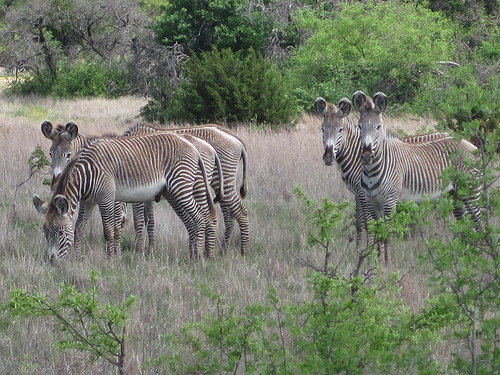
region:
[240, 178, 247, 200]
The bushy tip of a zebra's tail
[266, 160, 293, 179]
Tall dry brown grass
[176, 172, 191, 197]
Brown and white stripe on a zebra's flank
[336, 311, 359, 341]
Small green leaves on a scrub bush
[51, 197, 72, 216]
A zebra's ear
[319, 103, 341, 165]
A zebra's muzzle, facing forward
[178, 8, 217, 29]
Green leaves on a tree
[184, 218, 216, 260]
Three zebra hind legs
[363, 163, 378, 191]
Brown and white stripe pattern on a zebra's neck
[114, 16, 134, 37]
Bare tree branches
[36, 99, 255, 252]
zebras in the field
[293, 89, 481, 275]
zebras in the field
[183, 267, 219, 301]
dry grass in field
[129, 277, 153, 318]
dry grass in field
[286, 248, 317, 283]
dry grass in field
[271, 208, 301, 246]
dry grass in field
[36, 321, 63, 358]
dry grass in field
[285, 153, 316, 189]
dry grass in field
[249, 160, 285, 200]
dry grass in field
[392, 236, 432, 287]
dry grass in field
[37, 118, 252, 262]
A pair of zebras grazing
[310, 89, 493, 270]
A pair of zebras staring at photographer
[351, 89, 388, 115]
Pair of round zebra ears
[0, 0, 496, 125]
Trees behind the zebras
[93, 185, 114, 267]
Stripes on zebra leg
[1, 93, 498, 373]
Grassy area for grazing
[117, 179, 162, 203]
Solid white patch on zebra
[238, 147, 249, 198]
Skinny zebra tail with furry end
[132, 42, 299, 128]
Tall green bush behind zebras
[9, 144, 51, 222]
Small tree branch beside zebra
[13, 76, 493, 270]
several zebra in the wild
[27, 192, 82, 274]
the head of a zebra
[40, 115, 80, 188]
the head of a zebra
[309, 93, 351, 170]
the head of a zebra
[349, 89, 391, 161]
the head of a zebra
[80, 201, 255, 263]
the legs of three zebras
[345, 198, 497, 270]
the legs of two zebras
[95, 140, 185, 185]
the stripes of a zebra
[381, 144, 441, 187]
the stripes of a zebra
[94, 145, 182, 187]
the fur of a zebra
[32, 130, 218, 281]
A zebra eating.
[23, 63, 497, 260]
zebras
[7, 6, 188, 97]
A tree without any leaves.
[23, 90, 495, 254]
Black and white striped animals.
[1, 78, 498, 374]
Dry light brown grass.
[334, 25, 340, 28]
A green leaf on a plant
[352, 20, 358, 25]
A green leaf on a plant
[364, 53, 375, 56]
A green leaf on a plant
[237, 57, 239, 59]
A green leaf on a plant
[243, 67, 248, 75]
A green leaf on a plant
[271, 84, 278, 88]
A green leaf on a plant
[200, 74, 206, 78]
A green leaf on a plant